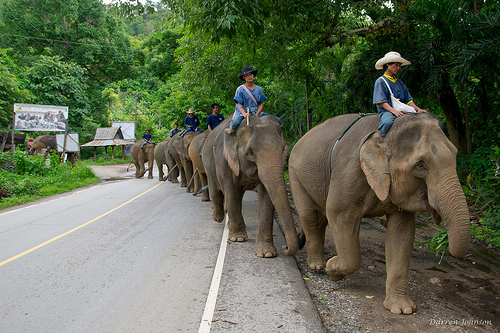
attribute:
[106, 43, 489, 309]
elephant — old, tired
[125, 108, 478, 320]
elephants — six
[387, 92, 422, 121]
bag — white 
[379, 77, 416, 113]
bag — white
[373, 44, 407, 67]
hat. — white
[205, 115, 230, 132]
shirt — blue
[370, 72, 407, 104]
shirt — blue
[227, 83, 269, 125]
suit — blue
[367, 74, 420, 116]
shirt — blue 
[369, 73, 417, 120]
shirt — blue